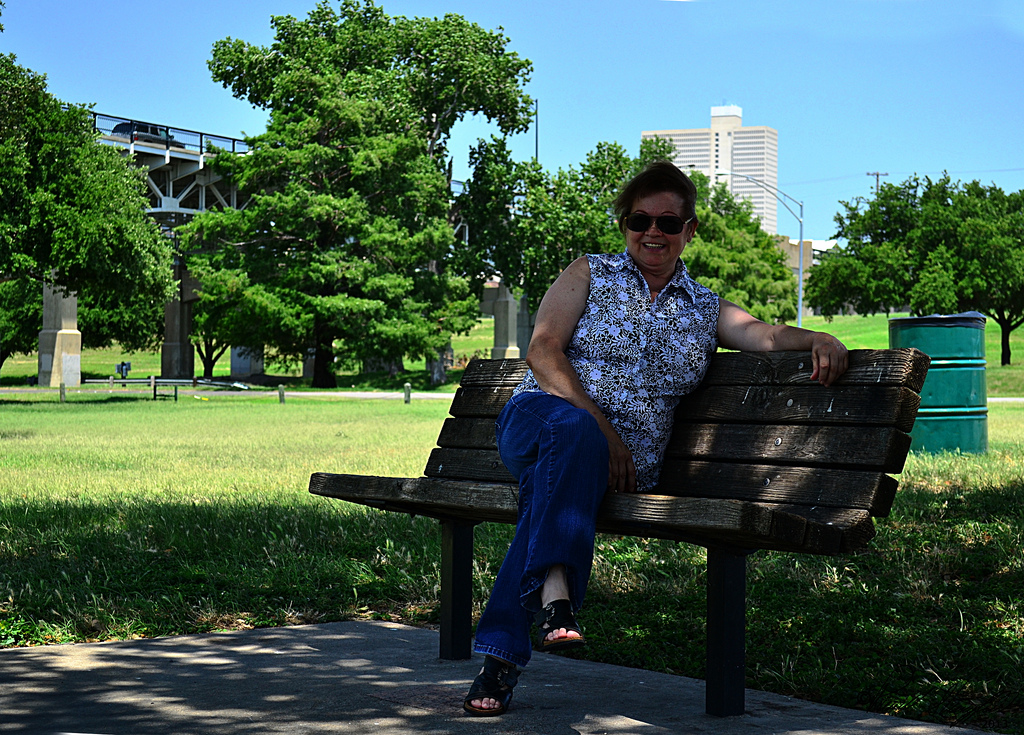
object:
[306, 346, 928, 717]
bench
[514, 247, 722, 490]
floral shirt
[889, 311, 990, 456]
trash bin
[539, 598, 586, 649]
sandal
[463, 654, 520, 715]
sandal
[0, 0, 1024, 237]
blue sky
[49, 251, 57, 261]
green leaves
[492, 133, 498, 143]
green leaves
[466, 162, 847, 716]
woman